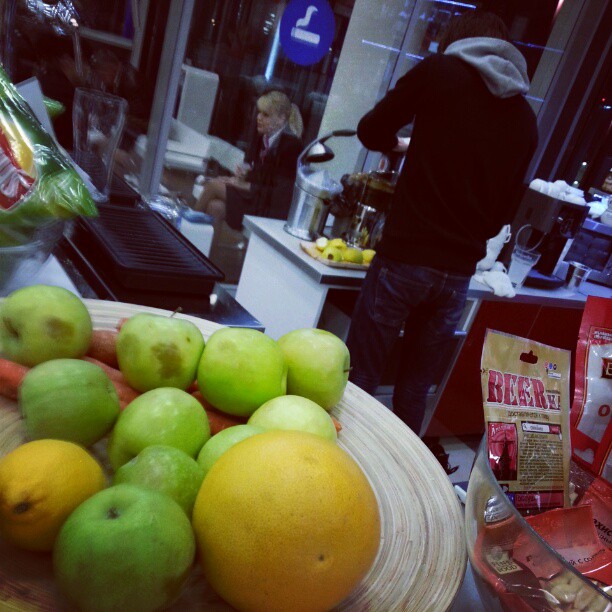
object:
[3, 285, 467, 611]
dish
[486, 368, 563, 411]
design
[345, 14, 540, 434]
man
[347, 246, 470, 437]
jeans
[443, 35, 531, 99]
hood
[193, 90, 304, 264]
woman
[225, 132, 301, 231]
suit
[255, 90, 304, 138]
hair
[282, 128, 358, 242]
juicer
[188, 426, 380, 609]
grapefruit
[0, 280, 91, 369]
apple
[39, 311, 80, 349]
bruise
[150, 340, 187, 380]
bruise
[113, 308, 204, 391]
apple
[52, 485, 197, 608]
apple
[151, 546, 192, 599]
bruise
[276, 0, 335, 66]
sign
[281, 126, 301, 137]
insignia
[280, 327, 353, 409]
apple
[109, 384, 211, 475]
apple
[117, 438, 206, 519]
apple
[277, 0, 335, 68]
round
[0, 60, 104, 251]
blurry bags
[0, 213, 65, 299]
bowl